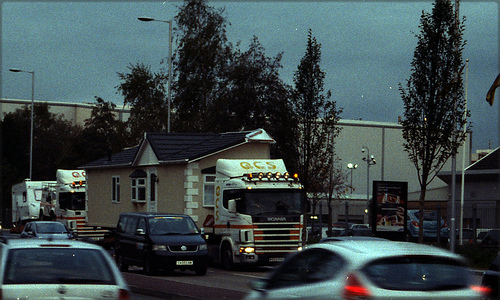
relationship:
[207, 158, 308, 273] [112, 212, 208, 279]
semi beside van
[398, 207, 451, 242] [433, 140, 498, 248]
car beside building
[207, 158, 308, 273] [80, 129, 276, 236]
semi pulling house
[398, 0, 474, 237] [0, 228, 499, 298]
tree are next to road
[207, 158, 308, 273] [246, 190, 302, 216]
semi has a windshield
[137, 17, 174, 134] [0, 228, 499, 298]
lightpole next to road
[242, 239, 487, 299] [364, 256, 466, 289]
car has window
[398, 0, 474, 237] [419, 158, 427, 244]
tree have trunk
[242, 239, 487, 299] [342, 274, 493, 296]
car has light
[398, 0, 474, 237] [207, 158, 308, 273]
tree are behind semi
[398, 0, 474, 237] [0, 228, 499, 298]
tree are beside road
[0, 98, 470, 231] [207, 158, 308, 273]
warehouse behind semi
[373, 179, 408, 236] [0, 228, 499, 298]
sign beside road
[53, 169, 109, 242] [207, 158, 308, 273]
semi behind semi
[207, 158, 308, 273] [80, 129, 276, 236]
semi carrying house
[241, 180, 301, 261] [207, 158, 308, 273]
front of semi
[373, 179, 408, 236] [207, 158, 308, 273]
sign behind semi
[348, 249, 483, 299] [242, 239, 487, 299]
back of car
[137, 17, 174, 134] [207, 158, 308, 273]
lightpole behind semi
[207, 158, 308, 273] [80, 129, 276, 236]
semi has half a house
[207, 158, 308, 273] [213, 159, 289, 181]
semi has spoiler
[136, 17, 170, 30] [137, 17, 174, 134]
street light on lightpole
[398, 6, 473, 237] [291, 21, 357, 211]
tree next to tree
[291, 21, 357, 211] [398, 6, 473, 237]
tree next to tree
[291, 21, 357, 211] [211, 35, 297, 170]
tree next to tree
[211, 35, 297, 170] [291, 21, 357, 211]
tree next to tree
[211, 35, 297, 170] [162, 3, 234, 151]
tree next to tree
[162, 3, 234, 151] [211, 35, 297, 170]
tree next to tree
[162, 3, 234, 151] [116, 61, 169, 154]
tree next to tree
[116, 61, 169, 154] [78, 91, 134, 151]
tree next to tree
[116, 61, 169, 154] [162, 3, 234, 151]
tree next to tree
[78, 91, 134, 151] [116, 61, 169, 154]
tree next to tree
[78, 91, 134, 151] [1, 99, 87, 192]
tree next to tree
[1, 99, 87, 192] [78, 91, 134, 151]
tree next to tree